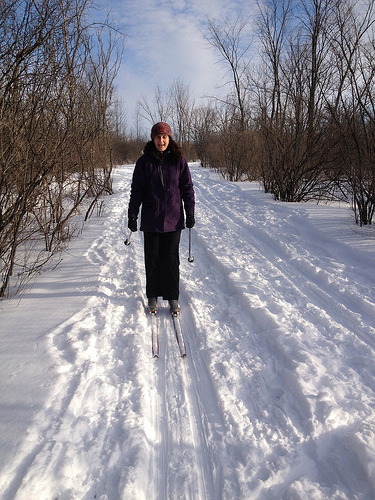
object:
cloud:
[0, 0, 375, 147]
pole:
[188, 228, 195, 262]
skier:
[128, 122, 195, 317]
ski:
[151, 313, 159, 358]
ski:
[172, 314, 187, 357]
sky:
[0, 0, 374, 141]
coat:
[128, 139, 195, 233]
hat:
[151, 122, 172, 140]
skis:
[151, 316, 186, 358]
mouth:
[158, 144, 165, 147]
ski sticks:
[124, 230, 133, 246]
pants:
[144, 232, 181, 300]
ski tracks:
[147, 309, 221, 500]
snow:
[0, 159, 375, 500]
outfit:
[128, 138, 196, 300]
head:
[151, 122, 172, 152]